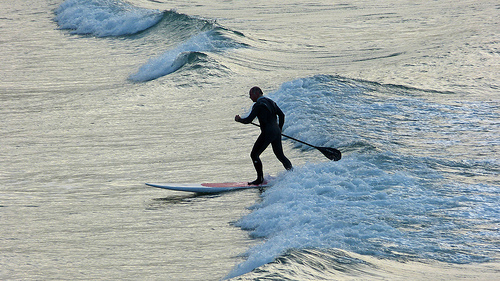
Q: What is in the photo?
A: Surfer.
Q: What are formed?
A: Waves.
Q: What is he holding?
A: Paddle.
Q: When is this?
A: Daytime.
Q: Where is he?
A: In the ocean.